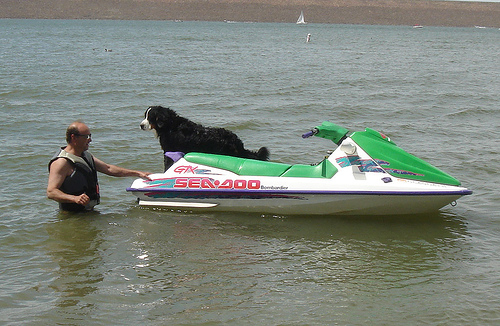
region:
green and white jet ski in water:
[118, 119, 480, 216]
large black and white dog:
[124, 87, 274, 177]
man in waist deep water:
[39, 108, 136, 225]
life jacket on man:
[48, 142, 110, 214]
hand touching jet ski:
[124, 161, 160, 199]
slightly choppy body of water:
[219, 56, 416, 116]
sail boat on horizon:
[281, 8, 326, 30]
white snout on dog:
[136, 116, 153, 131]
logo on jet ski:
[164, 170, 269, 196]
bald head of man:
[59, 118, 98, 139]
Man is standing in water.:
[39, 112, 139, 231]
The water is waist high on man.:
[33, 115, 150, 241]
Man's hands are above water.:
[36, 144, 169, 225]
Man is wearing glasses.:
[65, 131, 94, 142]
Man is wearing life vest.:
[42, 145, 112, 214]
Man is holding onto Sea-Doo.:
[111, 120, 483, 235]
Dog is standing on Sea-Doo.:
[123, 98, 277, 206]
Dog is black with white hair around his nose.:
[134, 102, 269, 178]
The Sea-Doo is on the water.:
[121, 107, 478, 247]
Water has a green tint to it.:
[4, 13, 498, 324]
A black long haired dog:
[137, 101, 273, 165]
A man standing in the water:
[45, 118, 150, 210]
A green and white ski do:
[123, 120, 473, 215]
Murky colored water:
[61, 225, 408, 302]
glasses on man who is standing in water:
[65, 130, 87, 140]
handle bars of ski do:
[300, 117, 350, 143]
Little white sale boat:
[292, 8, 307, 25]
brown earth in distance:
[320, 2, 467, 16]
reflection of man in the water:
[42, 209, 104, 308]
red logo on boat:
[172, 176, 263, 190]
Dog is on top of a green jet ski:
[115, 90, 283, 181]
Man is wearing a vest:
[33, 127, 121, 224]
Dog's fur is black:
[128, 96, 283, 179]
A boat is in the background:
[288, 5, 328, 38]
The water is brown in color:
[19, 58, 494, 304]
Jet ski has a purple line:
[136, 169, 474, 212]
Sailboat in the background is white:
[289, 3, 317, 28]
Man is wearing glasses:
[58, 118, 103, 149]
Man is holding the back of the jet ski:
[119, 162, 179, 199]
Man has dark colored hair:
[58, 126, 88, 146]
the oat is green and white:
[170, 152, 456, 249]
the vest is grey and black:
[41, 126, 143, 228]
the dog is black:
[135, 107, 293, 158]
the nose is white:
[130, 101, 162, 142]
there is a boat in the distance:
[287, 12, 329, 30]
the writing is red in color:
[174, 171, 268, 189]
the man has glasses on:
[59, 122, 107, 153]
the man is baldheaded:
[59, 127, 101, 159]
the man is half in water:
[38, 145, 116, 231]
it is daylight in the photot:
[4, 5, 488, 268]